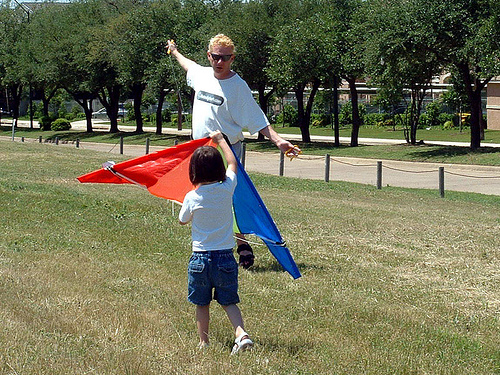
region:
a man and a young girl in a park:
[164, 30, 299, 355]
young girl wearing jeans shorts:
[186, 249, 238, 310]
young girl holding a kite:
[78, 133, 300, 278]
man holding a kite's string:
[165, 35, 195, 143]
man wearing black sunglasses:
[207, 51, 234, 62]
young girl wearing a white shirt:
[176, 172, 236, 250]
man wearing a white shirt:
[184, 65, 266, 150]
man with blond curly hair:
[206, 33, 236, 74]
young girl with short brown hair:
[188, 143, 226, 185]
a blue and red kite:
[77, 130, 302, 285]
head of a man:
[193, 26, 245, 78]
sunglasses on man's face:
[200, 41, 230, 71]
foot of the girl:
[220, 325, 260, 370]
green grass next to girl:
[300, 310, 346, 351]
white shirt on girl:
[175, 170, 245, 250]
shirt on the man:
[172, 70, 242, 130]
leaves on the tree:
[361, 16, 446, 66]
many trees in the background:
[20, 15, 155, 100]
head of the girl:
[176, 131, 227, 182]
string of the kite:
[158, 70, 193, 115]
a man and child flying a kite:
[47, 17, 318, 361]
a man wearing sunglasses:
[203, 30, 237, 88]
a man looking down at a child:
[161, 28, 266, 223]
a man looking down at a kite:
[72, 30, 302, 290]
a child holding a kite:
[98, 133, 295, 355]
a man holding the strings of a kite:
[85, 29, 299, 208]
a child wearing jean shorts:
[166, 145, 251, 312]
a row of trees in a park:
[3, 0, 495, 129]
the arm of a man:
[158, 33, 192, 83]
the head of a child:
[183, 145, 225, 190]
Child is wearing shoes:
[192, 331, 254, 354]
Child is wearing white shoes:
[187, 332, 254, 353]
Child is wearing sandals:
[187, 330, 257, 358]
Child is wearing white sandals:
[193, 329, 253, 357]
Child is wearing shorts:
[184, 246, 245, 307]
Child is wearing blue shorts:
[184, 245, 244, 307]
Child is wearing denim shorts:
[182, 248, 244, 308]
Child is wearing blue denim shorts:
[186, 249, 242, 306]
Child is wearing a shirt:
[176, 169, 243, 254]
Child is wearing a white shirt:
[175, 170, 243, 254]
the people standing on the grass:
[164, 32, 301, 354]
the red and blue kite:
[76, 133, 301, 279]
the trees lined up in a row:
[0, 1, 498, 153]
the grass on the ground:
[0, 108, 498, 373]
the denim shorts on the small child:
[185, 249, 240, 305]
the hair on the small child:
[187, 147, 227, 187]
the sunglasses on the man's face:
[207, 51, 232, 61]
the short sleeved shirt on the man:
[185, 63, 270, 145]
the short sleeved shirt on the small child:
[177, 169, 237, 251]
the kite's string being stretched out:
[167, 39, 192, 141]